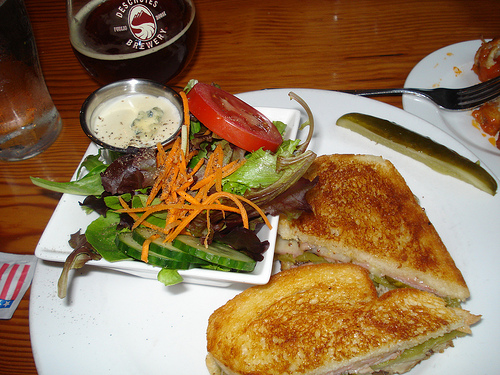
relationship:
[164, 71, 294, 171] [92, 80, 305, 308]
tomato on salad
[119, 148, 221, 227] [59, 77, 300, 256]
carrots on salad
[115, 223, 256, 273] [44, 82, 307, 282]
cucumber slices on salad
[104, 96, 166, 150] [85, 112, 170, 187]
dressing in container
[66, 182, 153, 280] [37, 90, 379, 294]
greens in bottom of salad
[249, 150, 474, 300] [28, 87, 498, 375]
sandwich cut on plate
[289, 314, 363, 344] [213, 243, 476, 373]
bread on sandwich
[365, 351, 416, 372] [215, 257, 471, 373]
meat on sandwich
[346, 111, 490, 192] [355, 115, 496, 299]
pickle on plate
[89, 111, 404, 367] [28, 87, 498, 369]
food on plate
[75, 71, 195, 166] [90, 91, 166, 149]
bowl of dressing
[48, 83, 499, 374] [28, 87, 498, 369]
food on plate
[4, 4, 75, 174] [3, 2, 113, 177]
glass in corner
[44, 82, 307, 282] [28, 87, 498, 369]
salad on plate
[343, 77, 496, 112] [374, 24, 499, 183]
fork on plate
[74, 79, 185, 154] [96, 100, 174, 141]
cup of dip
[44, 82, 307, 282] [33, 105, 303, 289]
salad on plate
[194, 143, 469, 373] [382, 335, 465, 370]
sandwich with lettuce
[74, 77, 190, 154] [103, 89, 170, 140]
cup filled with dressing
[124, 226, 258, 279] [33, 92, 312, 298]
slices on plate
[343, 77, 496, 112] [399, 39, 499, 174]
fork on plate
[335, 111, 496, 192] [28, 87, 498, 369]
pickle on plate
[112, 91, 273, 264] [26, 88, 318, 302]
carrots on salad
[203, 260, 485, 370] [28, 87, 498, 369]
sandwich half on plate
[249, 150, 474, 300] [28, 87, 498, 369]
sandwich cut on plate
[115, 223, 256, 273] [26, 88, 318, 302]
cucumber slices on salad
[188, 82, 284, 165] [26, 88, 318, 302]
tomato on salad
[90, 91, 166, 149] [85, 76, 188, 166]
dressing in metal dish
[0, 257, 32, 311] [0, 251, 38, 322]
flag on packet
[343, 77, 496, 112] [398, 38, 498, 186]
fork on plate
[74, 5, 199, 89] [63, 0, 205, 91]
beer in glass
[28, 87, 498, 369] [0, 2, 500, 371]
plate in table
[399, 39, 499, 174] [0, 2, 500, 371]
plate in table